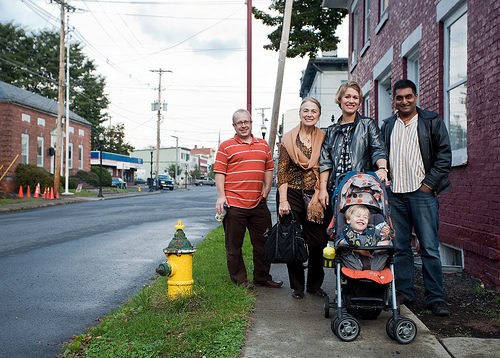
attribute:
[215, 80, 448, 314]
people — standing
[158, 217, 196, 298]
fire hydrant — yellow green, yellow, green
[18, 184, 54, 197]
cones — traffic, orange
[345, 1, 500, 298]
building — brick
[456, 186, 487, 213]
brick — red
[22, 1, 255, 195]
power lines — tall, brown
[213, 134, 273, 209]
shirt — striped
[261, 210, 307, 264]
bag — black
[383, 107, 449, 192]
jacket — black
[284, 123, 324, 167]
scarf — brown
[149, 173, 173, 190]
truck — black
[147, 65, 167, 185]
pole — tall, telephone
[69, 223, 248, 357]
grass — green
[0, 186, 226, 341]
city street — paved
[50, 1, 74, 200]
pole — tall, telephone